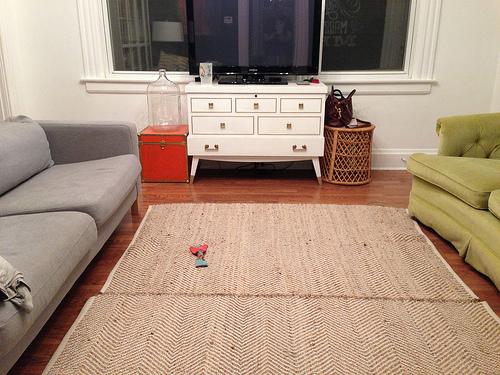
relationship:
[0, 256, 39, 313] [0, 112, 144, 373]
clothing on couch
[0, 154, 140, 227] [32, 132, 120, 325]
cushion on couch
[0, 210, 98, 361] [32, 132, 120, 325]
cushion on couch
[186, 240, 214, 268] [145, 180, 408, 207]
toy on floor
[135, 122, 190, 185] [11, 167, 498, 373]
chest on floor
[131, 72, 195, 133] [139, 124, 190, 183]
bottle on chest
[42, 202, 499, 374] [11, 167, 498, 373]
area rug on floor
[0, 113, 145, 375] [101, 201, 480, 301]
couch left of rug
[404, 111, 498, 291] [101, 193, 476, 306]
couch right of rug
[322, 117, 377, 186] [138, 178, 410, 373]
basket on ground